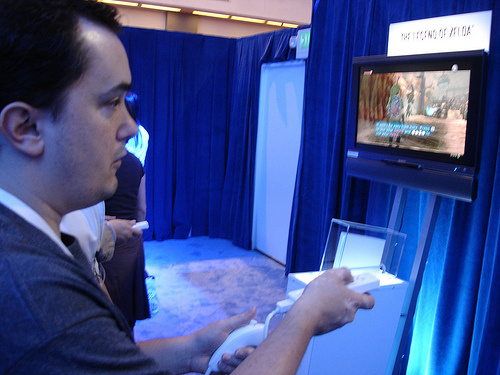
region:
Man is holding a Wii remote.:
[325, 262, 394, 328]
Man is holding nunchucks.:
[185, 319, 269, 374]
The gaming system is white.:
[298, 262, 408, 373]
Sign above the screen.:
[373, 13, 493, 59]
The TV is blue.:
[332, 50, 480, 201]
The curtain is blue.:
[141, 37, 243, 232]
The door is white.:
[251, 60, 310, 252]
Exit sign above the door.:
[288, 22, 323, 59]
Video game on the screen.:
[356, 67, 463, 157]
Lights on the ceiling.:
[148, 1, 302, 40]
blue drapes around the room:
[143, 31, 295, 260]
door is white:
[241, 49, 299, 292]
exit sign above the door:
[295, 26, 336, 92]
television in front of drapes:
[351, 39, 489, 194]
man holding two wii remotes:
[154, 262, 451, 358]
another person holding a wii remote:
[115, 203, 184, 241]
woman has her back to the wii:
[120, 175, 166, 342]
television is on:
[372, 63, 495, 164]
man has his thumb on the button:
[238, 298, 278, 328]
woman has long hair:
[125, 98, 150, 153]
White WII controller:
[208, 272, 389, 371]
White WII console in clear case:
[318, 215, 399, 280]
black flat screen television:
[344, 53, 481, 203]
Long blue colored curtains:
[108, 48, 494, 373]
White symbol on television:
[345, 149, 363, 157]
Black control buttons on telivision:
[375, 157, 423, 175]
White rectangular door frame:
[249, 60, 296, 270]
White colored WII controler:
[127, 217, 148, 231]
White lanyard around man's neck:
[1, 190, 76, 258]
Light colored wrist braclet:
[104, 220, 119, 242]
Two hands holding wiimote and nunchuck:
[195, 249, 390, 372]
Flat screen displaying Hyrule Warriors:
[339, 44, 488, 212]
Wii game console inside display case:
[312, 214, 410, 264]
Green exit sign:
[278, 20, 332, 69]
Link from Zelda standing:
[337, 43, 492, 208]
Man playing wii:
[1, 0, 381, 373]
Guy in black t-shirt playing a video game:
[1, 0, 383, 370]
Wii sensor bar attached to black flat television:
[339, 38, 494, 206]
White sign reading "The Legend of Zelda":
[378, 11, 495, 61]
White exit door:
[240, 20, 318, 267]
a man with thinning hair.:
[3, 0, 376, 373]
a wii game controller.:
[202, 265, 382, 373]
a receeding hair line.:
[71, 16, 143, 69]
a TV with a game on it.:
[335, 45, 497, 214]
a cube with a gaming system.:
[310, 207, 415, 298]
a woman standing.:
[89, 105, 174, 362]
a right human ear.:
[0, 89, 52, 171]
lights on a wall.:
[98, 0, 299, 39]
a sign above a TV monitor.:
[372, 9, 494, 64]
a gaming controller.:
[125, 210, 159, 237]